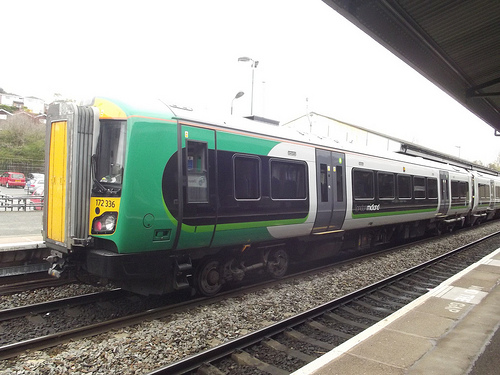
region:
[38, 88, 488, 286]
a green, white, yellow, and black passenger train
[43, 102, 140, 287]
the back of a passenger train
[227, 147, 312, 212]
windows on a passenger train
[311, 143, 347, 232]
doors on a passenger train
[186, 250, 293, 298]
wheels on a passenger train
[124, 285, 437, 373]
the rails on a train track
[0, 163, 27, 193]
a small red car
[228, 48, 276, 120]
tall lamp posts at a train station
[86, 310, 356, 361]
gravel between train tracks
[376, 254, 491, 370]
the loading ramp at a train station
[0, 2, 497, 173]
glowing light of day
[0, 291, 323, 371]
two sets of railroad tracks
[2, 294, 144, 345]
gravel inside of tracks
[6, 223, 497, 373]
gravel in between tracks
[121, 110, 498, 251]
green and white side of train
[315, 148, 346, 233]
gray double doors and windows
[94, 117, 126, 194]
window on front of train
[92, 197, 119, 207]
black numbers on yellow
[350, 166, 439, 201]
row of windows on train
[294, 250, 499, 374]
edge of train platform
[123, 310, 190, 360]
rocks in the train tracks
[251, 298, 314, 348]
rocks in the train tracks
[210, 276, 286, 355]
rocks in the train tracks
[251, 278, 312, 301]
rocks in the train tracks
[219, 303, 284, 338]
rocks in the train tracks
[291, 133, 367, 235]
train door is closed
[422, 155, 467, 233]
train door is closed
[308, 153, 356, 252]
train door is closed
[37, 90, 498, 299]
Train on train tracks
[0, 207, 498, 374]
Train tracks under and beside the train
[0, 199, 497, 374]
Gravel under and around the train tracks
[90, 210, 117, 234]
Headlight so train conductor can see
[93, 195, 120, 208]
Train number printed on the front of the train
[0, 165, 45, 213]
Cars parked in a parking lot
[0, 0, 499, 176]
Cloudy sky over the train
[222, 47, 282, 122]
Street lamps to illuminate the ground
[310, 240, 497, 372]
Train platform for travelers to wait on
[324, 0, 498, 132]
Roof to shade people from the elements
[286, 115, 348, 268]
train's door is gray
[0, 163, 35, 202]
the car is red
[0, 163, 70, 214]
the car is red